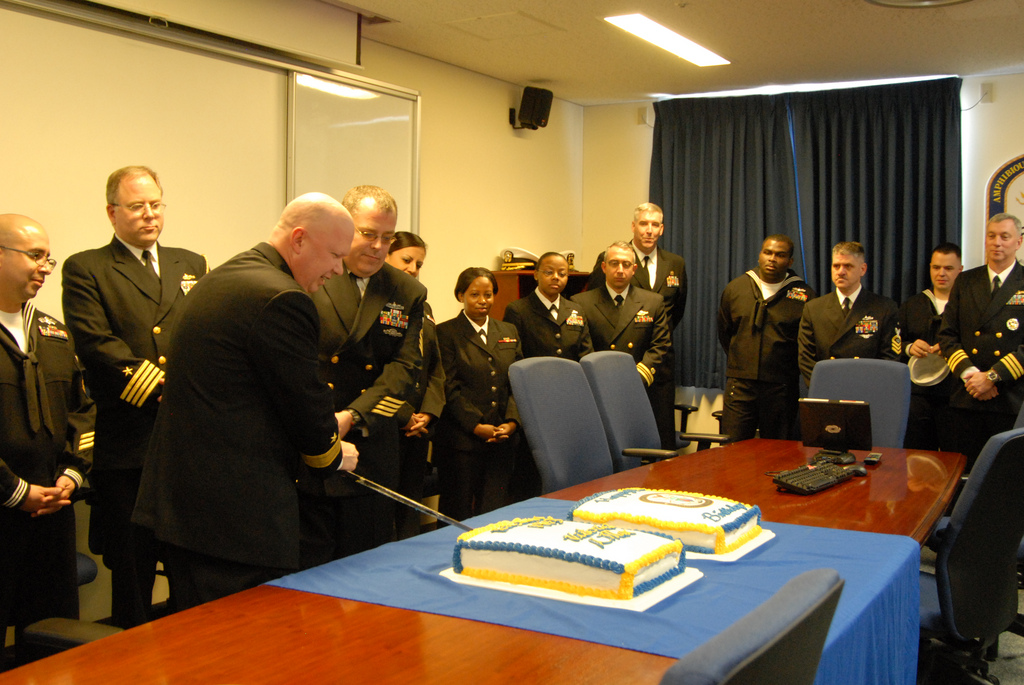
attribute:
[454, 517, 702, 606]
cake — sheet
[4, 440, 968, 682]
tablecloth — blue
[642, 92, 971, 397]
curtains — hanging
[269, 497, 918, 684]
tablecloth — blue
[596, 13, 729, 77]
light — shining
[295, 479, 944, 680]
cloth — table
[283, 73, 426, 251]
reflection — light